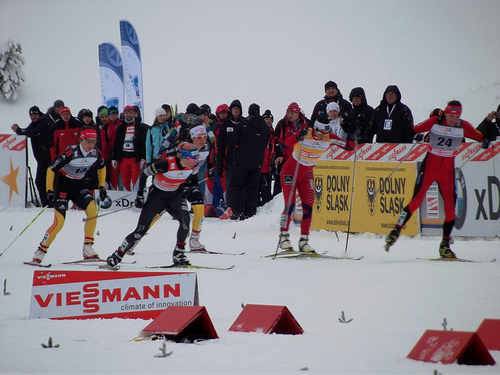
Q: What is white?
A: Snow.